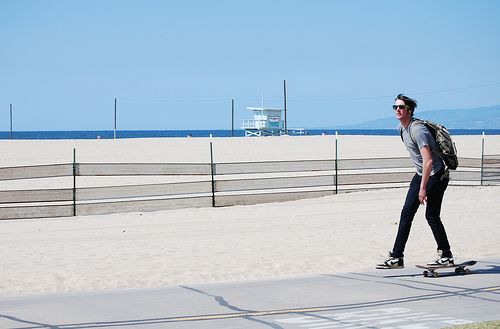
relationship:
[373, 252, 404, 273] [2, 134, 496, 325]
man's foot off ground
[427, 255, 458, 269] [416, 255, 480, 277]
sneaker on skateboard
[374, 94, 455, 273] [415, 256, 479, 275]
man on skateboard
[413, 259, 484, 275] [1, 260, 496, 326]
skateboard on roadway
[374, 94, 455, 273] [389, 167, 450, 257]
man wearing jeans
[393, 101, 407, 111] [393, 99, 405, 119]
sunglasses on man's face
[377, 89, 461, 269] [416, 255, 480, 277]
guy riding skateboard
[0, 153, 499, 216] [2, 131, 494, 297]
fence in sand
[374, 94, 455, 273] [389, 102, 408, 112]
man wearing sunglasses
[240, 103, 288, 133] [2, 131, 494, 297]
lifeguard stand in sand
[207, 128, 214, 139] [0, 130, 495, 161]
trash can in sand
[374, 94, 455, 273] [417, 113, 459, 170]
man wearing backpack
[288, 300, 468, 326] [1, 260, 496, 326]
bike written on roadway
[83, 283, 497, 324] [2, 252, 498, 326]
divider on sidewalk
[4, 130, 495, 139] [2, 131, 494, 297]
ocean beyond sand